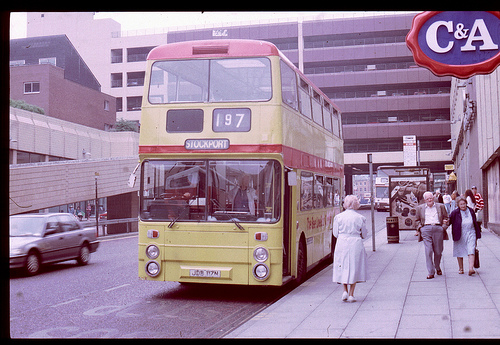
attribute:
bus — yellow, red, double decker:
[136, 38, 342, 298]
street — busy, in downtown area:
[7, 181, 409, 333]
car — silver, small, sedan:
[9, 211, 102, 278]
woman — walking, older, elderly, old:
[330, 194, 367, 301]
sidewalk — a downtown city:
[224, 213, 499, 342]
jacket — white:
[331, 211, 367, 286]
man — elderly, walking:
[418, 191, 445, 278]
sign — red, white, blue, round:
[409, 14, 496, 76]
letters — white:
[425, 19, 496, 56]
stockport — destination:
[187, 141, 227, 148]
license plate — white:
[189, 269, 222, 279]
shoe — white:
[341, 291, 349, 302]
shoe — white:
[349, 293, 358, 305]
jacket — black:
[449, 204, 482, 242]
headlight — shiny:
[256, 249, 268, 260]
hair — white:
[342, 193, 361, 212]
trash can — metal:
[385, 214, 401, 245]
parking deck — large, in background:
[28, 14, 451, 208]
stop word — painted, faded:
[31, 322, 173, 344]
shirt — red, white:
[471, 192, 483, 209]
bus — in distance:
[368, 168, 395, 209]